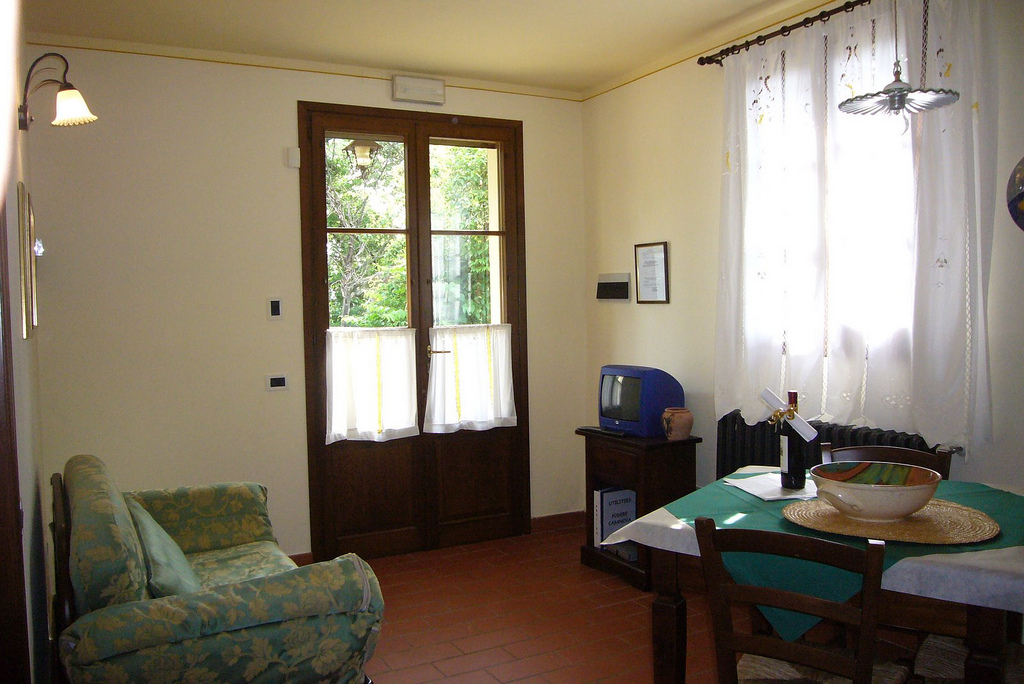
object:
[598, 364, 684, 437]
tv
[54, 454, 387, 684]
couch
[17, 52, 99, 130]
light fixture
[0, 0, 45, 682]
wall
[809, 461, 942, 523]
bowl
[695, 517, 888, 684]
chair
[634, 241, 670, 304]
picture frame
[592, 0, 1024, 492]
wall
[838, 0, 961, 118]
light fixture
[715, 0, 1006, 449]
window curtain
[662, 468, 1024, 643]
table cloth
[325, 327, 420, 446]
curtain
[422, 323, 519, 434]
curtain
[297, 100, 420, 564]
door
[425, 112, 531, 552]
door